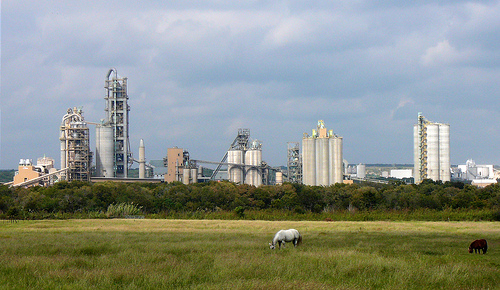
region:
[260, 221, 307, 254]
horse grazing in the field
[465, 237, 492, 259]
brown horse in a field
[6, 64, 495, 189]
industrial buildings in the background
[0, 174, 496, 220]
dense area of small trees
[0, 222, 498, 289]
large grass field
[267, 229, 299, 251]
white horse grazing in the grass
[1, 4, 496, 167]
cloud covered sky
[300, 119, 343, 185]
gray industrial building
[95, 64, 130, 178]
gray tower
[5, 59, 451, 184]
factory buildings in the background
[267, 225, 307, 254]
white horse in grassy field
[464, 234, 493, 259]
black horse in grassy field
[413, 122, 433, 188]
stairs going up side of large white tower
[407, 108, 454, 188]
two white towers side by side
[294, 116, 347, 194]
building made up of three seprate towers attached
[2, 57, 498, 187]
factory with many towers and large machines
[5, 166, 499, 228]
line of trees separating a field from a factor y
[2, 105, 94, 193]
white conveyor belt leading up to open sided tower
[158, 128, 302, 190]
three separate buildings in mill with conveyor belt leading from one to another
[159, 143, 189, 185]
tan structure that's multiple stories high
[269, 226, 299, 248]
a white horse in a field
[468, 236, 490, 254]
a brown horse in a field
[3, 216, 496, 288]
A large grassy field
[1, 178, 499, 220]
A large row of trees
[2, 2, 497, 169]
A grey, cloudy sky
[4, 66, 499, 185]
A large factory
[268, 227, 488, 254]
a pair of horses in a field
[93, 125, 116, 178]
A very large silo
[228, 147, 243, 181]
A very large silo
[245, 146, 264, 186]
A very large silo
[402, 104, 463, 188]
large building behind field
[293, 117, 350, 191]
large building behind field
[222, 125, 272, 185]
large building behind field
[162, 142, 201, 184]
large building behind field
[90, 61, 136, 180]
large building behind field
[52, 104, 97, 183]
large building behind field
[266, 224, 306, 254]
white horse in field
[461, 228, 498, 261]
brown horse in field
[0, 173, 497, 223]
row of trees behind field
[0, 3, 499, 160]
blue sky with clouds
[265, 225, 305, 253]
Horse grazing in field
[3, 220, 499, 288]
grass covered pasture field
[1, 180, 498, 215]
Trees along pasture field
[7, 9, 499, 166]
Grey clouds in sky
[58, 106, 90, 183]
Large agricultural product processing tower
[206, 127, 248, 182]
Metal conveyer belt on side of tower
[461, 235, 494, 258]
Horse grazing in field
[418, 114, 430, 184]
Metal stairway of storage tower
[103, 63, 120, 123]
Metal carrying pipe for argicultural products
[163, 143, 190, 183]
Brown brick building